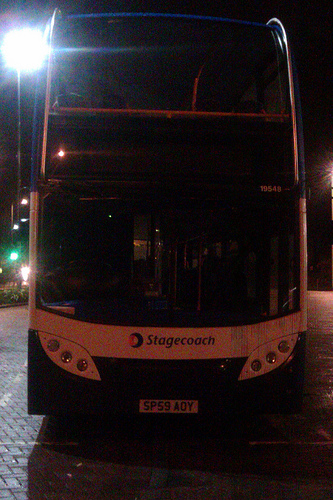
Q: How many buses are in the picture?
A: One.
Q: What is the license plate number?
A: SP59 AOY.